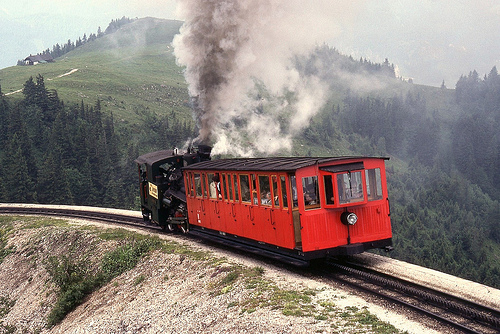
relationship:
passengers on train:
[209, 181, 221, 196] [133, 138, 394, 274]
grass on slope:
[43, 235, 157, 320] [1, 211, 466, 333]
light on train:
[344, 211, 359, 228] [133, 138, 394, 274]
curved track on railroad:
[3, 201, 144, 233] [1, 201, 499, 332]